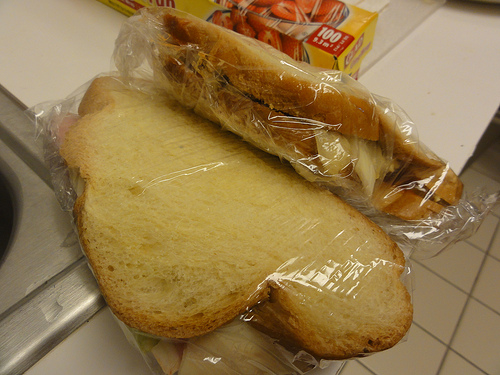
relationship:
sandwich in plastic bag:
[132, 2, 475, 224] [51, 66, 401, 354]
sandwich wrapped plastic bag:
[132, 2, 475, 224] [51, 66, 401, 354]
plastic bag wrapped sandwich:
[51, 66, 401, 354] [132, 2, 475, 224]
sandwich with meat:
[132, 2, 475, 224] [311, 114, 402, 197]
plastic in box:
[266, 5, 308, 36] [262, 4, 383, 68]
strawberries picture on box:
[218, 3, 333, 55] [262, 4, 383, 68]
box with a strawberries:
[262, 4, 383, 68] [218, 3, 333, 55]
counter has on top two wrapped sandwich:
[408, 40, 492, 122] [34, 6, 460, 365]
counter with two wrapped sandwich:
[408, 40, 492, 122] [34, 6, 460, 365]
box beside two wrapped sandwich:
[262, 4, 383, 68] [34, 6, 460, 365]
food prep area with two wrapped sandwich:
[0, 0, 490, 362] [34, 6, 460, 365]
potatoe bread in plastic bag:
[60, 67, 412, 355] [51, 66, 401, 354]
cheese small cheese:
[356, 159, 380, 198] [356, 159, 380, 198]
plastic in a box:
[266, 5, 308, 36] [262, 4, 383, 68]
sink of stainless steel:
[8, 156, 73, 336] [3, 160, 79, 323]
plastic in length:
[266, 5, 308, 36] [262, 4, 383, 68]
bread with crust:
[132, 2, 475, 224] [162, 11, 387, 136]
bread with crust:
[79, 78, 250, 320] [107, 282, 283, 350]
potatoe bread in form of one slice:
[78, 68, 360, 314] [79, 78, 250, 320]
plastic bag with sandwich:
[130, 3, 474, 244] [132, 2, 475, 224]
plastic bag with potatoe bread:
[51, 66, 401, 354] [60, 67, 412, 355]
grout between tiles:
[442, 342, 457, 352] [418, 258, 500, 359]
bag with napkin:
[174, 338, 280, 374] [235, 331, 270, 357]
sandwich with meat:
[132, 2, 475, 224] [311, 122, 351, 174]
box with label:
[262, 4, 383, 68] [309, 18, 353, 61]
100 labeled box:
[319, 26, 345, 49] [262, 4, 383, 68]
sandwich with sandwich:
[132, 2, 475, 224] [132, 2, 475, 224]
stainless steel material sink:
[3, 160, 79, 323] [8, 156, 73, 336]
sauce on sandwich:
[390, 164, 436, 206] [132, 2, 475, 224]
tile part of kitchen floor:
[418, 258, 500, 359] [375, 220, 499, 374]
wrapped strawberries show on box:
[219, 2, 312, 55] [262, 4, 383, 68]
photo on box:
[224, 4, 333, 65] [262, 4, 383, 68]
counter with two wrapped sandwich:
[408, 40, 492, 122] [21, 4, 452, 323]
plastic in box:
[266, 5, 308, 36] [105, 4, 378, 82]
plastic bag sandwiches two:
[51, 66, 401, 354] [21, 4, 452, 323]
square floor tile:
[395, 251, 472, 344] [418, 258, 500, 359]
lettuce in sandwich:
[186, 51, 241, 96] [132, 2, 475, 224]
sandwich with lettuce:
[132, 2, 475, 224] [186, 51, 241, 96]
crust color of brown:
[162, 11, 387, 136] [212, 38, 296, 94]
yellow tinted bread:
[74, 84, 239, 283] [79, 78, 250, 320]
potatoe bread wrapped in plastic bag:
[60, 67, 412, 355] [51, 66, 401, 354]